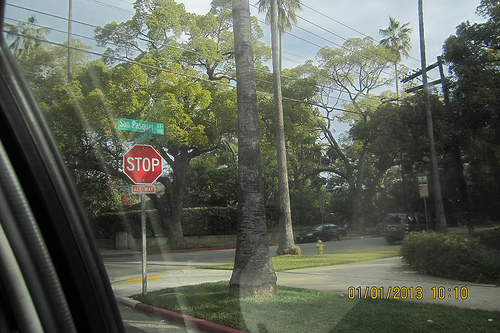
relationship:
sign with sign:
[98, 132, 182, 214] [83, 99, 182, 139]